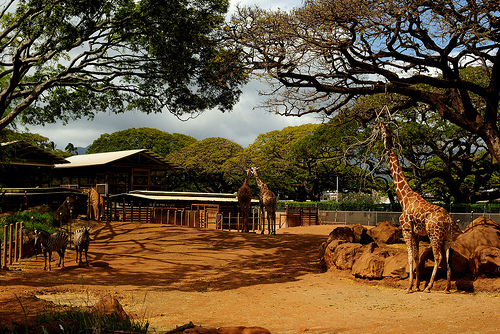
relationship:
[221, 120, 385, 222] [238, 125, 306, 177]
leaves of tree